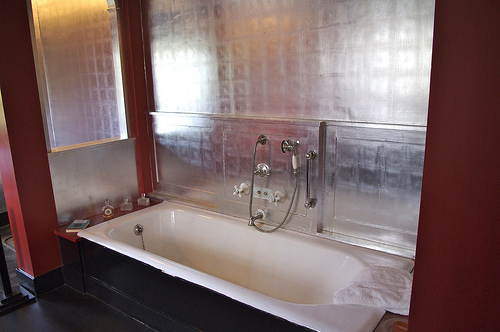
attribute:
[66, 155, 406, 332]
bathtub — white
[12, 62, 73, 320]
walls — red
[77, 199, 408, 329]
bathtub — black, white, porcelain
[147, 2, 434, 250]
wall — silver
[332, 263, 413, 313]
towel — white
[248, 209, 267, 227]
faucet — white, silver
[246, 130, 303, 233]
showerhead — white, silver